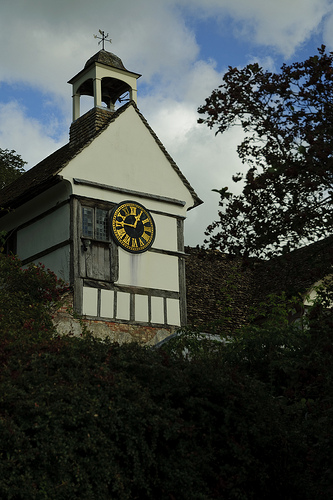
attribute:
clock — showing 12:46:
[93, 179, 195, 273]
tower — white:
[5, 29, 210, 338]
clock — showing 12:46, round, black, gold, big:
[109, 201, 155, 253]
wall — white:
[75, 196, 188, 329]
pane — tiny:
[83, 206, 88, 210]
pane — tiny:
[87, 209, 92, 214]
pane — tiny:
[96, 215, 100, 220]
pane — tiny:
[100, 232, 103, 237]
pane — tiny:
[87, 229, 91, 233]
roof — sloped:
[0, 99, 202, 211]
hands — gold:
[116, 209, 142, 227]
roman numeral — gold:
[143, 225, 153, 232]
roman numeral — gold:
[140, 231, 150, 240]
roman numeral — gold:
[130, 237, 138, 247]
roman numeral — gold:
[123, 234, 129, 243]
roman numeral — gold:
[129, 205, 136, 215]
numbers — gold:
[113, 204, 153, 251]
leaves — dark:
[194, 60, 328, 339]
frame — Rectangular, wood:
[73, 277, 188, 332]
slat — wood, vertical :
[95, 287, 102, 314]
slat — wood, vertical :
[112, 290, 118, 318]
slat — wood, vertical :
[128, 294, 136, 321]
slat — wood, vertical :
[147, 296, 152, 322]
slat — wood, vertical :
[162, 297, 168, 324]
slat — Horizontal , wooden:
[72, 175, 186, 206]